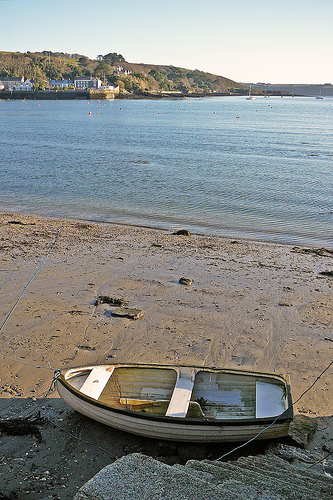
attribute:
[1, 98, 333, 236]
body of water — large, blue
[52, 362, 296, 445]
boat — wooden, white, small, grounded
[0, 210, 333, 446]
shore — wet, brown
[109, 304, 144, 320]
rock — gray, square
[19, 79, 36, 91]
building — white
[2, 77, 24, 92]
building — white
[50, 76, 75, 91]
building — white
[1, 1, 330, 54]
sky — clear, blue, bright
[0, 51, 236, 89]
mountain — large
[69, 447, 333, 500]
steps — concrete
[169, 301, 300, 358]
sand — wet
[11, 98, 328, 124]
bouys — red